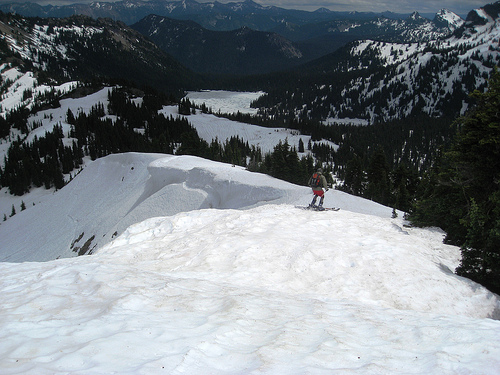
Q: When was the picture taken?
A: Daytime.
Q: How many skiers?
A: One.